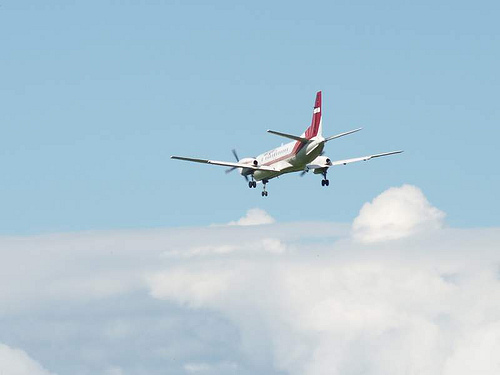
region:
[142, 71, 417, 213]
Plane above the clouds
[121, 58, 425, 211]
Red and white airplane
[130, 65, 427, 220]
Plane flying in the air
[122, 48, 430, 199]
Plane flying above the clouds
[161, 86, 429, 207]
Airplane at cruising altitude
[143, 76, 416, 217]
Airplane with landing gear down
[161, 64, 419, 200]
Airplane with red and white writing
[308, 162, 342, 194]
Airplane wheels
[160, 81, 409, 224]
Propeller airplane flying above the clouds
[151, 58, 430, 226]
Airplane cruising in the sky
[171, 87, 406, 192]
the plane is white and red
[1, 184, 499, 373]
the cloud are white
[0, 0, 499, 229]
the sky is blue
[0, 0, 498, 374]
the sky is cloudy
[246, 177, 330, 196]
the planes wheels are extended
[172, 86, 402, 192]
the plane is flying high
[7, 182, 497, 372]
the clouds are fluffy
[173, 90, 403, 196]
the plane has a red line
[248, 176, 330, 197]
the plane has three wheels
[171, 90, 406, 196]
the plane is large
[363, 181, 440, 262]
large fluffy white cloud in sky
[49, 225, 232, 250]
overcast gray cloud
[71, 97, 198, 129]
crystal clear blue skies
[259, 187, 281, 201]
black wheels on plane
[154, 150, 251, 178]
white and black plane wing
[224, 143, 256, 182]
black propeller on plane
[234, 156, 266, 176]
single engine on side of plane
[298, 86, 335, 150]
red tail on wing of plane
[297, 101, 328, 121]
white marking on red wing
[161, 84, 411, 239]
small plane flying in the sky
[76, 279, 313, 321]
the clouds are white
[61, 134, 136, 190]
the sky is blue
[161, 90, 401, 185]
the plane is white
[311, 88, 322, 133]
the tail of plane is red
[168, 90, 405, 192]
plane has two engines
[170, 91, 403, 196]
the plane has two wings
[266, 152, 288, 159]
windows on the side of plane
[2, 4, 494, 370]
its daytime in the photo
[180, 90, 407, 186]
planes is high in the sky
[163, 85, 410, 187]
plane is white and red in color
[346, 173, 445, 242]
a cloud in the sky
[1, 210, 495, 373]
fluffy white clouds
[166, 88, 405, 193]
an airplane flying above the clouds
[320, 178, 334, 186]
wheels on an airplane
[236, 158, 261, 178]
an airplane engine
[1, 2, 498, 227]
a bright blue sky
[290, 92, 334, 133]
a red tail on an airplane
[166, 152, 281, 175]
the wing of an airplane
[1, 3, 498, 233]
a clear sunny day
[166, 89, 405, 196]
a red and white airplane flying